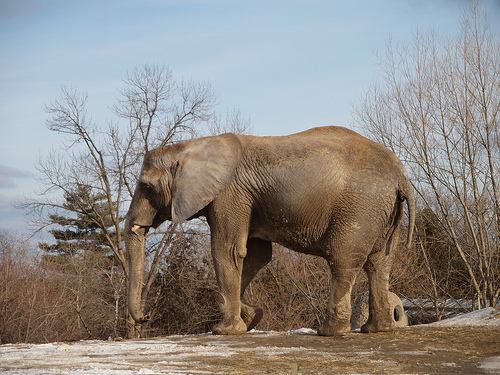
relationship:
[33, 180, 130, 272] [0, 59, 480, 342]
tree standing in background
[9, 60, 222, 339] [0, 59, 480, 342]
tree standing in background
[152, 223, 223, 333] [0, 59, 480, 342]
tree standing in background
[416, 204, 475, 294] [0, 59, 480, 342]
tree standing in background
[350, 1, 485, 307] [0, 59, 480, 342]
tree standing in background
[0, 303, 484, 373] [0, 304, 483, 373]
dirt covering ground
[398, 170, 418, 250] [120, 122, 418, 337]
tail belonging to elephant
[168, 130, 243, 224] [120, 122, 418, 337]
ear belonging to elephant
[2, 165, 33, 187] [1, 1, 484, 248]
cloud hanging in sky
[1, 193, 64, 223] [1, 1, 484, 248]
cloud hanging in sky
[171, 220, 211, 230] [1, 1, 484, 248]
cloud hanging in sky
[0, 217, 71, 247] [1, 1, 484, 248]
cloud hanging in sky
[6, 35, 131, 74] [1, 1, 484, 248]
cloud hanging in sky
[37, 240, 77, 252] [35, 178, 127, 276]
branch growing on tree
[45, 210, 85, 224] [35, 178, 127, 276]
branch growing on tree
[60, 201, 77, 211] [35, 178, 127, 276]
branch growing on tree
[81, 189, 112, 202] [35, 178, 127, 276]
branch growing on tree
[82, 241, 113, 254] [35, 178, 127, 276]
branch growing on tree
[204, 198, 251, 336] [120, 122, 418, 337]
leg belonging to elephant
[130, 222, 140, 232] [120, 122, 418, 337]
tusk belonging to elephant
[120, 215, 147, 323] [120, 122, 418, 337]
trunk belonging to elephant